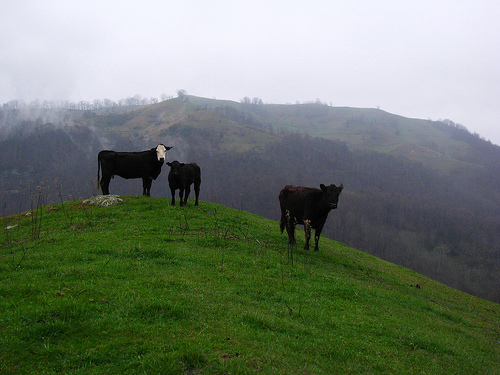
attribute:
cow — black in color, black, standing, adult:
[93, 142, 174, 198]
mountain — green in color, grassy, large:
[4, 195, 499, 372]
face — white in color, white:
[152, 141, 173, 164]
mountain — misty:
[4, 94, 496, 307]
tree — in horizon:
[232, 91, 272, 118]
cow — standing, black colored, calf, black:
[164, 156, 211, 204]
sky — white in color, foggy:
[0, 2, 500, 146]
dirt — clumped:
[208, 333, 258, 363]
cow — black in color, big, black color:
[269, 174, 345, 250]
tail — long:
[273, 184, 291, 234]